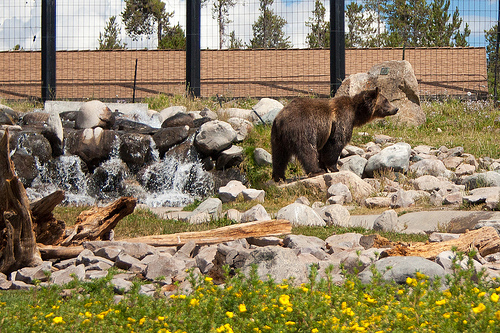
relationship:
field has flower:
[2, 70, 484, 332] [73, 272, 467, 331]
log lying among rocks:
[359, 214, 497, 273] [3, 229, 498, 317]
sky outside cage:
[4, 3, 494, 48] [1, 0, 498, 102]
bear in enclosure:
[264, 85, 401, 185] [2, 1, 466, 327]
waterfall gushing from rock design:
[24, 154, 218, 223] [3, 110, 498, 295]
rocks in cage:
[2, 61, 493, 293] [1, 1, 498, 332]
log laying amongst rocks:
[29, 194, 281, 266] [8, 180, 471, 313]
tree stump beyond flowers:
[0, 132, 42, 278] [40, 291, 230, 325]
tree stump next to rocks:
[0, 132, 42, 278] [15, 227, 316, 277]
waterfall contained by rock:
[54, 154, 218, 201] [218, 179, 268, 201]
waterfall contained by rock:
[54, 154, 218, 201] [196, 193, 226, 220]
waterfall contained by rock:
[54, 154, 218, 201] [273, 203, 326, 233]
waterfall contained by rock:
[54, 154, 218, 201] [325, 178, 359, 209]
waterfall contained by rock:
[54, 154, 218, 201] [195, 120, 240, 150]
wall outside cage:
[4, 50, 493, 105] [1, 0, 498, 102]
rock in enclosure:
[349, 256, 451, 291] [2, 1, 466, 327]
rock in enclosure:
[33, 122, 232, 209] [2, 1, 466, 327]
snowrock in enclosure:
[367, 133, 414, 202] [2, 1, 466, 327]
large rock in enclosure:
[38, 267, 92, 287] [6, 119, 477, 294]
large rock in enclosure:
[193, 118, 243, 148] [2, 1, 466, 327]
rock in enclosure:
[458, 170, 498, 191] [2, 1, 466, 327]